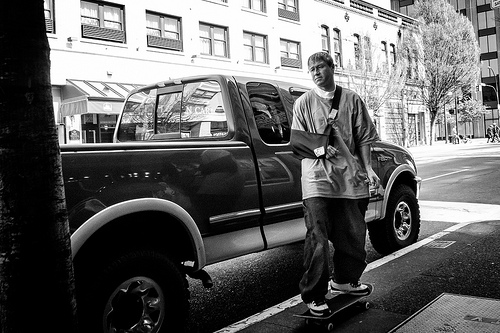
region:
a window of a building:
[241, 34, 252, 59]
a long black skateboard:
[290, 276, 375, 331]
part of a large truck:
[57, 64, 430, 330]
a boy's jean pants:
[295, 192, 367, 299]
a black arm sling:
[284, 85, 343, 165]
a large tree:
[406, 0, 479, 139]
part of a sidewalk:
[223, 214, 498, 331]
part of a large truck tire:
[80, 238, 191, 331]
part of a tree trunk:
[0, 0, 79, 331]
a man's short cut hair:
[308, 50, 333, 65]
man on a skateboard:
[280, 48, 385, 331]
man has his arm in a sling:
[288, 43, 383, 317]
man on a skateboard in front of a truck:
[55, 44, 433, 331]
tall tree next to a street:
[388, 0, 482, 150]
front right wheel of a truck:
[364, 172, 422, 259]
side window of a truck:
[241, 74, 293, 149]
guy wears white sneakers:
[284, 46, 382, 330]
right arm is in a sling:
[283, 45, 348, 165]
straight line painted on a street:
[208, 215, 485, 332]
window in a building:
[143, 8, 182, 56]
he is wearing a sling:
[286, 123, 338, 168]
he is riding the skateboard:
[303, 276, 365, 324]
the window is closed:
[148, 85, 187, 140]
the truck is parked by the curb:
[386, 206, 424, 256]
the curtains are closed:
[197, 24, 230, 55]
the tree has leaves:
[434, 29, 469, 70]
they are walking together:
[485, 120, 498, 144]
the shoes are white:
[321, 273, 372, 300]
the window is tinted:
[256, 90, 281, 132]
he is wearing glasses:
[305, 60, 331, 72]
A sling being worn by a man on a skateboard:
[288, 128, 337, 160]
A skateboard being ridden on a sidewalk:
[292, 281, 377, 327]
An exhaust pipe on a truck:
[188, 265, 215, 290]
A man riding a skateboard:
[288, 50, 383, 327]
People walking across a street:
[483, 123, 498, 145]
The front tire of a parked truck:
[371, 185, 422, 250]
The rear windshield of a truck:
[106, 76, 231, 141]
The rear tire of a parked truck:
[72, 248, 192, 332]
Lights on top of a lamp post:
[478, 61, 499, 103]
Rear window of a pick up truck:
[243, 80, 293, 146]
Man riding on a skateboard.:
[270, 44, 382, 327]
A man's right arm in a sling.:
[289, 54, 349, 166]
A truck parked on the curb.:
[37, 53, 430, 330]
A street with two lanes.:
[418, 158, 498, 197]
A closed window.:
[233, 27, 267, 65]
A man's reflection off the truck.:
[175, 136, 251, 267]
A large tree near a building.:
[401, 3, 475, 150]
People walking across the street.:
[483, 124, 498, 146]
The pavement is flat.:
[419, 161, 499, 210]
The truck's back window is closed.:
[115, 86, 228, 136]